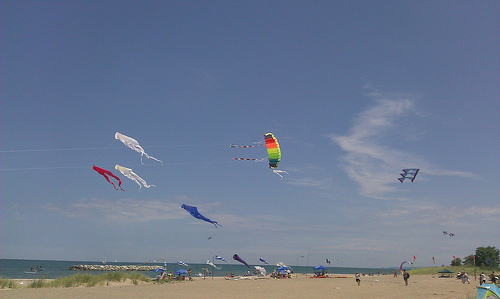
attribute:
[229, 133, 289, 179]
kite — flying, rainbow colored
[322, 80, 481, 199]
cloud — white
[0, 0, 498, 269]
sky — blue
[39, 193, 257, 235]
cloud — white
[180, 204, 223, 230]
kite — flying, blue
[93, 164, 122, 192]
kite — red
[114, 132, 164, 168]
kite — white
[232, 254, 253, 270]
wind sock — purple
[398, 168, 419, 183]
kite — flying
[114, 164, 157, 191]
kite — flying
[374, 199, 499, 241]
cloud — white